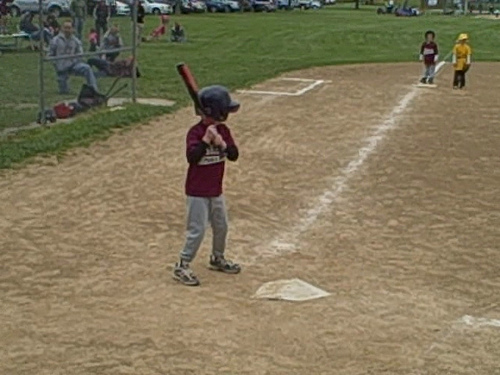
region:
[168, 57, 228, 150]
Baseball hat in child's hands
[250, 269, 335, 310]
White dirty home plate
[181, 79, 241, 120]
Black helmet on child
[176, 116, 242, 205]
Red shirt on child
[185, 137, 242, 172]
Black undershirt on child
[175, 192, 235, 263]
Gray pants on child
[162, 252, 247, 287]
Black and white shoes on child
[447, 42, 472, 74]
Yellow shirt of child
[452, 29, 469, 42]
Yellow hat on child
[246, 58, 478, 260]
White foul line on field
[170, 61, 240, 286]
Young boy up at bat prepared to swing.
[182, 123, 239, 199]
boy's shirt is red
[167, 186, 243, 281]
boy's pants are gray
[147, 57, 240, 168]
boy is holding a bat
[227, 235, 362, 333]
the base has dirt on it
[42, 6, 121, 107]
man watching the boy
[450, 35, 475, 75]
boy's shirt is yellow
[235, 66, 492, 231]
white line on field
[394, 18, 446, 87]
boy standing on base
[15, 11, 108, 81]
man behind a fence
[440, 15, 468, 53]
boy wearing a hat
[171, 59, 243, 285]
batter standing at plate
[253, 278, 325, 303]
white home plate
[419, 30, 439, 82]
child standing on base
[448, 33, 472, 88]
third baseman waiting for pitch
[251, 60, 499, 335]
white lines in the dirt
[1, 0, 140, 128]
a fence behind the batter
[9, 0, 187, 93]
people watching the game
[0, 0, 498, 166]
grass near the baseball field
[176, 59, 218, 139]
baseball bat in the boy's hands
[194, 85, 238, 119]
helmet on the batter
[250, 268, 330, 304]
a white base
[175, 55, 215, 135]
a red and black baseball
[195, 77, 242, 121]
a black baseball helmet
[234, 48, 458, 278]
a long white line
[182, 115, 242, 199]
a boy's long sleeve shirt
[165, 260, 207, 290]
a boy's tennis shoe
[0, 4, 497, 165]
a large section of green grass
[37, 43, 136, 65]
a long white pole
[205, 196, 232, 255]
the leg of a boy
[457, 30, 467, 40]
a yellow hat